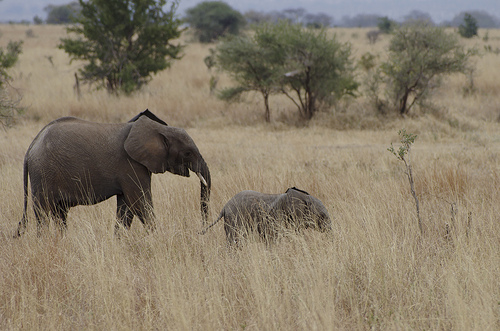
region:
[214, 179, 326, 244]
small baby elephant in front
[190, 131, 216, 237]
long brown elephant trunk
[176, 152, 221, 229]
long brown elephant trunk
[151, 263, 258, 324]
the grass is dry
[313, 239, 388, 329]
the grass is dry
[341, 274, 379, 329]
the grass is dry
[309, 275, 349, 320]
the grass is dry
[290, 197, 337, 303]
the grass is dry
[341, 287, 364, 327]
the grass is dry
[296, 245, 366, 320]
the grass is dry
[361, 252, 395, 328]
the grass is dry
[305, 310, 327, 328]
the grass is dry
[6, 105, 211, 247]
Large elephant in a field of wheat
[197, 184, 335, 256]
small elephant in a field of wheat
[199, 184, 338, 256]
small elephant walking in front of large elephant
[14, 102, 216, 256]
large elephant walking in front of small elephant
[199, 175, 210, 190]
tusks of the large elephant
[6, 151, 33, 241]
large elephants tail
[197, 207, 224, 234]
small elephants tail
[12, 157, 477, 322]
field of golden wheat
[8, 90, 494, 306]
field the elephants are walking in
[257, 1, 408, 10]
grey colored sky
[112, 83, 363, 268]
the elephants are visible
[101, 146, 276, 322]
the elephants are visible